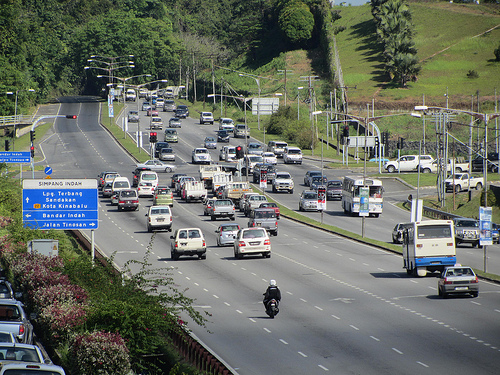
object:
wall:
[178, 58, 500, 210]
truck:
[402, 219, 457, 277]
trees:
[0, 2, 236, 138]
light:
[29, 115, 77, 179]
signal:
[149, 131, 158, 159]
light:
[149, 131, 158, 142]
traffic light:
[29, 130, 36, 158]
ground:
[412, 104, 498, 171]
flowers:
[0, 236, 135, 375]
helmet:
[268, 279, 276, 286]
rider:
[263, 279, 281, 311]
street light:
[414, 105, 500, 272]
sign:
[0, 151, 31, 163]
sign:
[44, 166, 53, 175]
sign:
[251, 96, 280, 115]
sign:
[347, 135, 375, 147]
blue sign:
[22, 188, 99, 230]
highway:
[13, 95, 500, 375]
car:
[116, 188, 140, 212]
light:
[131, 200, 138, 204]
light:
[118, 200, 125, 203]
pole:
[91, 230, 95, 271]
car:
[145, 205, 173, 233]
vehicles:
[402, 218, 480, 298]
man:
[263, 279, 281, 310]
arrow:
[330, 297, 355, 304]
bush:
[0, 161, 210, 372]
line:
[236, 309, 243, 313]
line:
[212, 294, 219, 298]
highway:
[39, 94, 138, 186]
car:
[437, 263, 480, 298]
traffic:
[99, 88, 500, 319]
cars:
[436, 263, 479, 299]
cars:
[169, 227, 206, 260]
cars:
[110, 188, 139, 211]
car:
[209, 199, 236, 221]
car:
[233, 227, 272, 260]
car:
[247, 207, 278, 236]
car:
[111, 176, 130, 194]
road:
[72, 198, 495, 370]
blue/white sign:
[22, 178, 99, 230]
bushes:
[54, 230, 213, 375]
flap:
[416, 266, 427, 276]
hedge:
[13, 286, 78, 375]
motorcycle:
[263, 291, 280, 319]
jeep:
[247, 208, 280, 236]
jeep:
[151, 187, 173, 207]